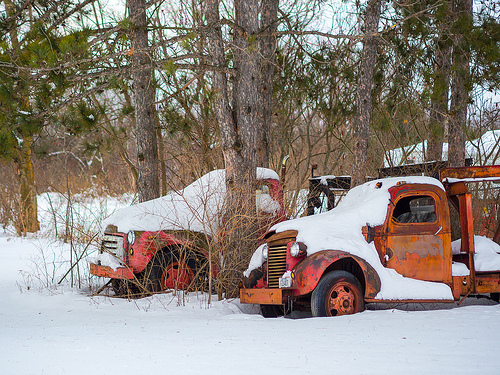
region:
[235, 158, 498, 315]
old truck sitting in snow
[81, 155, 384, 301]
second tree in snow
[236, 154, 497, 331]
old truck is very rusted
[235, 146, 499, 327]
old truck is red and orange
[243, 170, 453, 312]
snow on windshield and hood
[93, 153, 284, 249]
snow on windshield and hood of second truck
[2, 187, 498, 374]
ground is covered in snow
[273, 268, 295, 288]
license plate on front of truck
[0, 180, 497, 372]
snow is thick and white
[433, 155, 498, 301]
rack on back of truck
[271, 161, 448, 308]
Snow covering a truck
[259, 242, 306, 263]
Lights on a truck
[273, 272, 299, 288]
license plate on a truck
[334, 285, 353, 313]
orange rim on a truck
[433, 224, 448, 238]
silver handle on a truck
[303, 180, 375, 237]
Snow on the hood of a truck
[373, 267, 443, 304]
snow on the truck step board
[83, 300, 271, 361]
snow on the ground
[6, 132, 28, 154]
snow on the tree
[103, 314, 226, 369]
The snow is white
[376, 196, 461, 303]
The truck is orange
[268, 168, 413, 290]
The truck is covered in snow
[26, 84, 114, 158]
The tree needles are green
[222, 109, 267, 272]
The tree bark is gray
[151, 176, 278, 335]
The weeds are tall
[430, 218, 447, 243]
The door handle is metal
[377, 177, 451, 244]
The truck has a window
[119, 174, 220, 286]
The snow is on the hood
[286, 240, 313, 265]
The lights are off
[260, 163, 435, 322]
Snow is covering a truck.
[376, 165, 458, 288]
a truck has a red door.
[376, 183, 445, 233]
A truck has an open window.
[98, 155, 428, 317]
Trucks are covered in snow.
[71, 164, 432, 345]
Snow are covering two trucks.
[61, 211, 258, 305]
Branches are in growing in front of trucks.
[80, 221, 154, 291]
A truck has a silver grill.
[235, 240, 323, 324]
A truck has an rusty grill.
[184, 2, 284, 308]
A tree is standing between two trucks.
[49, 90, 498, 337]
Trees are surrounding two vintage trucks.